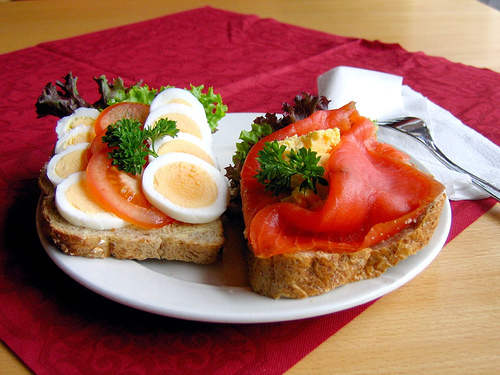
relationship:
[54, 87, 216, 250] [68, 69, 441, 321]
sandwhich on plate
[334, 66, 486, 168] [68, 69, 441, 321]
napkin near plate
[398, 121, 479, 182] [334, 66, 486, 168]
fork on napkin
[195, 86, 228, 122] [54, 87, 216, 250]
lettuce on sandwhich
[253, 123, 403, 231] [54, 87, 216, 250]
salmon on sandwhich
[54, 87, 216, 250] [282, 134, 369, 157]
sandwhich has eggs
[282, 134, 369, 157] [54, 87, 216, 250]
eggs on sandwhich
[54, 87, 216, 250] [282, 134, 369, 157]
sandwhich with eggs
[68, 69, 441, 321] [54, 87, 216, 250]
plate holding sandwhich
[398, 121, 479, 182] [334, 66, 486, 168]
fork on top of napkin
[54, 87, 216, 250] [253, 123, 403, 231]
sandwhich with salmon